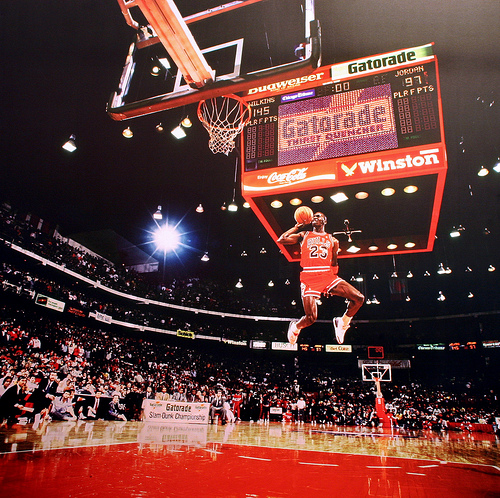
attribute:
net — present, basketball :
[197, 95, 252, 157]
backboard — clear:
[105, 0, 324, 122]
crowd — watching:
[1, 201, 499, 434]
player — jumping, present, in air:
[276, 205, 366, 347]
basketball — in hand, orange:
[293, 206, 315, 227]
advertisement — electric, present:
[277, 82, 399, 167]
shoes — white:
[286, 316, 351, 347]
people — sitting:
[1, 375, 130, 428]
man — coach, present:
[1, 376, 29, 431]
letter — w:
[352, 152, 379, 178]